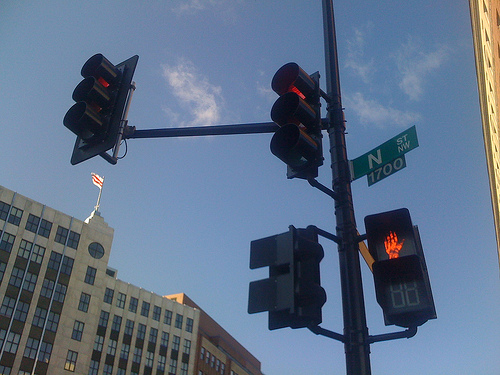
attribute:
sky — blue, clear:
[2, 2, 500, 373]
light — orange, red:
[263, 62, 328, 179]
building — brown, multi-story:
[0, 182, 267, 373]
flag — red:
[93, 170, 106, 192]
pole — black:
[323, 2, 379, 373]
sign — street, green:
[348, 122, 418, 188]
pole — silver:
[97, 192, 103, 205]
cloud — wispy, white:
[158, 53, 228, 131]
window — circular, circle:
[88, 240, 104, 259]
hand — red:
[383, 229, 407, 259]